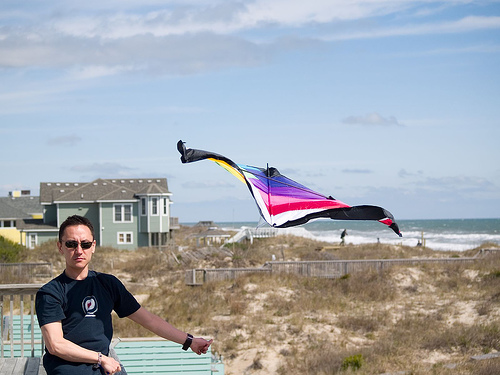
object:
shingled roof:
[39, 176, 169, 205]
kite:
[176, 139, 403, 239]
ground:
[0, 220, 497, 375]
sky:
[1, 0, 500, 221]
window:
[150, 195, 160, 216]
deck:
[3, 314, 224, 375]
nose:
[75, 242, 84, 256]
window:
[113, 204, 133, 223]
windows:
[116, 231, 133, 245]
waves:
[314, 226, 500, 251]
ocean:
[180, 218, 500, 251]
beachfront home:
[0, 176, 182, 250]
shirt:
[35, 269, 142, 375]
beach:
[173, 218, 500, 260]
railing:
[0, 283, 43, 362]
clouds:
[0, 2, 500, 150]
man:
[34, 214, 216, 375]